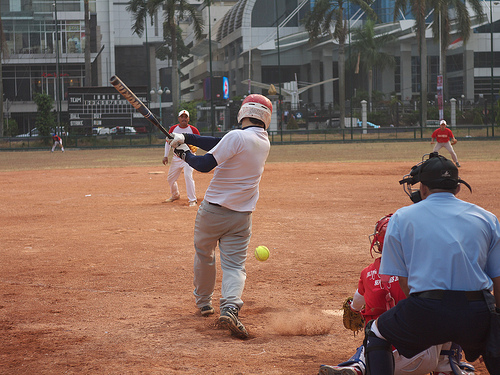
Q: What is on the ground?
A: Brown dirt.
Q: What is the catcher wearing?
A: A red uniform and mask.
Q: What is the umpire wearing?
A: Light blue shirt and blue shorts.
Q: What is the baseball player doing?
A: He is swinging the bat.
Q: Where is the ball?
A: In the air.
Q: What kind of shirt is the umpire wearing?
A: A blue short sleeved shirt.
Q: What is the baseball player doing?
A: Swinging the bat.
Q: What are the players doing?
A: Playing baseball.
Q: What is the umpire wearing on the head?
A: A blue baseball cap.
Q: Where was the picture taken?
A: A baseball field.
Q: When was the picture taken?
A: Daytime.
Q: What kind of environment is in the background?
A: Urban.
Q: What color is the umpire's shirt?
A: Light blue.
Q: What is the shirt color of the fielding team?
A: Red.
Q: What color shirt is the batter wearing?
A: White.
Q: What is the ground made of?
A: Dirt.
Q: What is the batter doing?
A: Swinging.